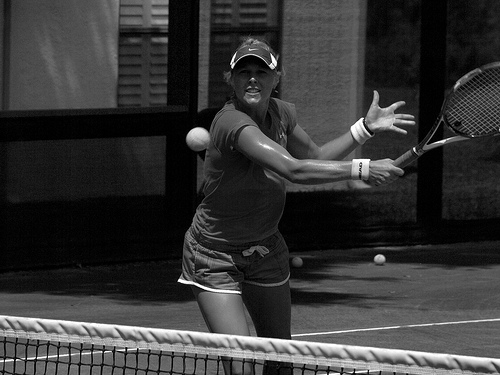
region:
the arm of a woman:
[223, 111, 355, 185]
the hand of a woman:
[362, 151, 408, 195]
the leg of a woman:
[181, 237, 266, 374]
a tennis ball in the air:
[184, 124, 216, 154]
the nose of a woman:
[245, 69, 259, 88]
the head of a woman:
[214, 33, 289, 114]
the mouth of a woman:
[242, 83, 264, 97]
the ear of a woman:
[271, 68, 288, 90]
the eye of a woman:
[254, 66, 269, 78]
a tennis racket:
[379, 57, 499, 184]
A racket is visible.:
[429, 48, 489, 140]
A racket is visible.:
[444, 82, 494, 118]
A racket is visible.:
[371, 13, 488, 199]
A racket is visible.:
[378, 63, 497, 141]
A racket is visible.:
[386, 80, 498, 187]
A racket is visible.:
[412, 91, 469, 232]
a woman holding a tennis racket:
[157, 37, 498, 293]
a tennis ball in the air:
[184, 113, 230, 158]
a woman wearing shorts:
[171, 42, 323, 307]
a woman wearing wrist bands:
[332, 76, 396, 216]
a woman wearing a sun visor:
[193, 26, 305, 113]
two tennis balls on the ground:
[284, 235, 404, 278]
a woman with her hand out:
[187, 32, 462, 247]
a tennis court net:
[11, 302, 352, 373]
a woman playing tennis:
[119, 42, 496, 372]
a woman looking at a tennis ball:
[116, 15, 376, 200]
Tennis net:
[0, 311, 498, 372]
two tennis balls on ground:
[282, 241, 420, 290]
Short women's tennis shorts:
[152, 203, 372, 309]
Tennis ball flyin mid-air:
[165, 101, 224, 171]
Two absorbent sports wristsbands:
[333, 90, 380, 202]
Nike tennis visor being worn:
[210, 33, 286, 76]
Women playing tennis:
[150, 26, 495, 192]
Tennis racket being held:
[365, 41, 495, 186]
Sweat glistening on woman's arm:
[210, 100, 400, 195]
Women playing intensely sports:
[171, 26, 493, 363]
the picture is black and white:
[21, 9, 478, 335]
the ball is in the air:
[143, 108, 384, 202]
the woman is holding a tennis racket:
[155, 26, 494, 181]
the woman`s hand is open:
[339, 77, 445, 142]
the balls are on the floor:
[280, 245, 400, 270]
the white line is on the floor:
[289, 299, 491, 346]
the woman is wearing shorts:
[136, 210, 300, 312]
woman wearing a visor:
[201, 27, 288, 79]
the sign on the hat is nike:
[235, 40, 262, 55]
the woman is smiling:
[212, 26, 301, 102]